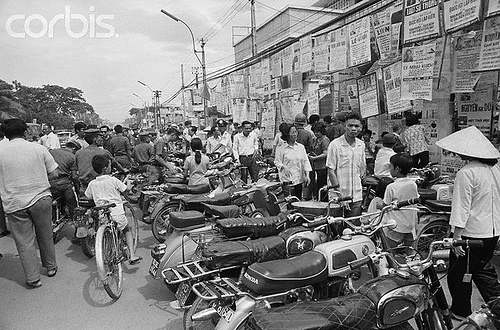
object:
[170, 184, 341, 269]
motorcycle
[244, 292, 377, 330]
seat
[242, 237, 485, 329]
bikes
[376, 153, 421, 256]
boy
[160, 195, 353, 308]
motorcycle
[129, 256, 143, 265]
flip flop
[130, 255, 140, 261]
foot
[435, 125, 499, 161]
hat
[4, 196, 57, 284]
pants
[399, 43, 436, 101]
flyer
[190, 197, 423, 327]
motorcycle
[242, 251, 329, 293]
moped's seat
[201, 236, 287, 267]
moped's seat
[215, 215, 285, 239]
moped's seat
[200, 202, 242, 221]
moped's seat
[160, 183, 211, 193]
moped's seat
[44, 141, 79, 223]
boy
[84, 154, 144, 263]
boy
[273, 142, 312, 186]
shirts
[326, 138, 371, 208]
torso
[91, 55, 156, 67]
clouds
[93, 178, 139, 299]
bicycle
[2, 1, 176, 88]
sky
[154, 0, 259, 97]
wires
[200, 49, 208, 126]
poles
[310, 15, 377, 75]
papers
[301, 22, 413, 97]
on wall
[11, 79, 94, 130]
tree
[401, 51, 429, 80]
event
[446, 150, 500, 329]
man